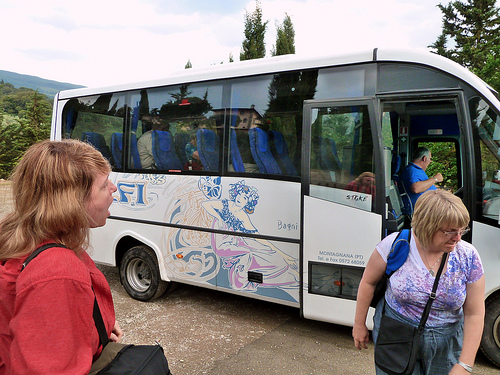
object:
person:
[0, 135, 122, 375]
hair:
[0, 137, 115, 264]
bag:
[85, 336, 177, 375]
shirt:
[0, 235, 114, 375]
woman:
[348, 185, 486, 375]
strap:
[381, 229, 414, 278]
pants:
[371, 296, 465, 373]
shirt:
[374, 231, 487, 327]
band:
[457, 357, 474, 371]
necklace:
[420, 248, 446, 278]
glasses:
[437, 225, 472, 240]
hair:
[409, 186, 472, 253]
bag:
[373, 314, 423, 375]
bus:
[48, 46, 500, 368]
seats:
[247, 127, 282, 175]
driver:
[398, 145, 446, 218]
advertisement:
[161, 174, 298, 302]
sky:
[0, 0, 500, 89]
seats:
[108, 131, 124, 170]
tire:
[118, 244, 168, 304]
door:
[297, 94, 384, 330]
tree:
[238, 0, 268, 60]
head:
[409, 186, 473, 254]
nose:
[452, 234, 464, 242]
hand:
[350, 323, 372, 350]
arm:
[353, 232, 393, 323]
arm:
[456, 247, 485, 365]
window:
[221, 67, 300, 183]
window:
[121, 77, 230, 177]